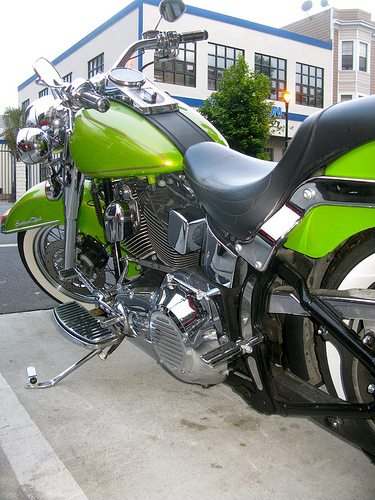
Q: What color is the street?
A: Gray.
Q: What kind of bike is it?
A: Motorbike.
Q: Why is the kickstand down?
A: To hold it up.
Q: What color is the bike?
A: Green.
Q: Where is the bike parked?
A: On the street.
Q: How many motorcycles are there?
A: One.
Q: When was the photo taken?
A: Daytime.